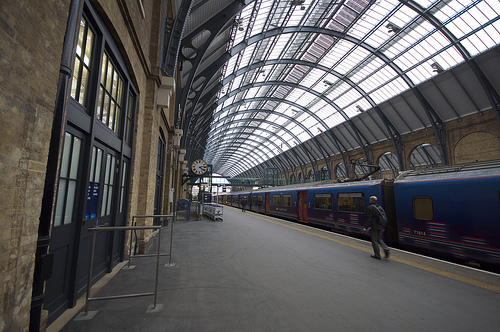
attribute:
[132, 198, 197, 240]
rails — metal, silver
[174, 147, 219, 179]
clock — white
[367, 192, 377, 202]
head — bald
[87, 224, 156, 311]
hand rail — silver, metal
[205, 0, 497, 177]
sky light — glass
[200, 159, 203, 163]
roman numerals — black